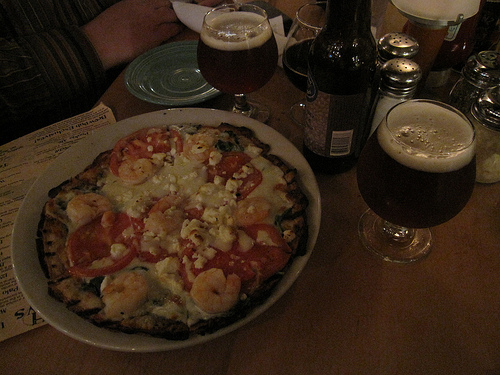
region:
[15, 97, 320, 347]
a round plate with a dinner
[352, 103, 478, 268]
a glass of drak beer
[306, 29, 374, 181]
a bottle of beer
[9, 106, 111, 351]
a paper under the plate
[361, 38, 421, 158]
salt and pepper shaker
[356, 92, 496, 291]
wood table under the glass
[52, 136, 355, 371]
wood table under the plate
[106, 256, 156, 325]
shrimp on the plate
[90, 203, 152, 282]
tomatoes on the plate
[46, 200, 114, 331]
bread crust on the plate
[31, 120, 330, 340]
Pizza on the plate.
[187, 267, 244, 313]
Shrimp on the pizza.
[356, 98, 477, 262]
Wine glass on the table.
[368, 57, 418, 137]
Salt shaker on the table.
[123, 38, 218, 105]
Green plate on the table.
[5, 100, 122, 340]
Menu on the table.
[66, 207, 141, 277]
Red tomato slice on the pizza.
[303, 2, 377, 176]
Dark bottle on the table.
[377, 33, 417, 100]
Silver metal caps on the containers.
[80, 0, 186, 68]
Hand resting on the table.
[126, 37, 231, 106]
ceramic food dish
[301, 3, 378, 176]
bottle of beer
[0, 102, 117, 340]
white paper menu with black writing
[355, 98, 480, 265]
glass of beer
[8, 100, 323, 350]
white ceramic plate sitting on table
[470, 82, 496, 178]
shaker of parmesean cheese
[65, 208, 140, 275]
tomato on a pizza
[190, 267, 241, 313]
cooked shrimp on a pizza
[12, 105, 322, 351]
pizza on a white plate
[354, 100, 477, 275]
glass of dark ale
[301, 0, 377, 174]
dark bottle of liquid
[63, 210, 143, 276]
tomato slice on pizza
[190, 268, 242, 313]
a shrimp on pizza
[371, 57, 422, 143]
salt shaker on table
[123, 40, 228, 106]
empty green saucer on table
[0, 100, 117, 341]
restaurant menu under plate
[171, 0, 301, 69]
folded napkin on table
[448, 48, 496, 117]
black pepper shaker on table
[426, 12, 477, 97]
upside down bottle of ketchup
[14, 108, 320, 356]
A personal pizza on the table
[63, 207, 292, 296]
The tomatoes are red on the pizza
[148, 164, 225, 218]
The cheese on the pizza is white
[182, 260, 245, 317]
A shrimp is pink on the pizza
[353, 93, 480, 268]
The glass is filled with beer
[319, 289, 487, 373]
The table is the color beige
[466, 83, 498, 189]
The container has Parmesan cheese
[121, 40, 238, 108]
The saucer is green on the table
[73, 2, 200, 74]
The hand of the person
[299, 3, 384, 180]
The bottle of the beer on the table